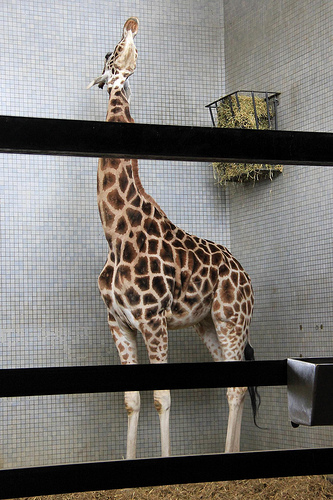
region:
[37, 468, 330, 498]
The hay on the ground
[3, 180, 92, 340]
The wall is made of tile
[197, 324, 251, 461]
The back legs of the giraffe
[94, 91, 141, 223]
The neck of the giraffe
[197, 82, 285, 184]
The bin of hay on the wall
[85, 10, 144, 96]
The head of the giraffe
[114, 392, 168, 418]
The knees of the giraffe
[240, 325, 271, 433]
The tail of the giraffe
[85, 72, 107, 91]
The ear of the giraffe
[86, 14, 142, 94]
the giraffe is holding his head up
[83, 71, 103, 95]
this is his ears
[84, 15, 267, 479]
this is a giraffe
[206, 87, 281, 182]
this is a basket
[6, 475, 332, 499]
this is the grass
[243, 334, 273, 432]
this is his tail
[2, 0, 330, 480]
this is tile on the wall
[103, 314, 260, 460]
these are the giraffes legs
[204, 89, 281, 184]
this is a basket with grass in it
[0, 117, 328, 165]
this is a rail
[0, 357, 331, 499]
A fence near the giraffe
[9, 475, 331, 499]
Hay beneath the giraffe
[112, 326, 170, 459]
The legs beneath the giraffe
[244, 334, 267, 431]
The tail of the giraffe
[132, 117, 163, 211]
The mane of the giraffe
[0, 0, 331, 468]
Walls around the giraffe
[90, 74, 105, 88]
The right ear of the giraffe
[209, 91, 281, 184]
A small cage full of hay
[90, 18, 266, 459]
A giraffe standing in an enclosure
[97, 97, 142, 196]
The giraffe has a long neck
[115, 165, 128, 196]
The spot is brown.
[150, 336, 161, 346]
The spot is brown.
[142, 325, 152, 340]
The spot is brown.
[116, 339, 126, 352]
The spot is brown.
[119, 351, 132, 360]
The spot is brown.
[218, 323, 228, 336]
The spot is brown.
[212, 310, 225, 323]
The spot is brown.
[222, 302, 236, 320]
The spot is brown.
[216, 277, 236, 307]
The spot is brown.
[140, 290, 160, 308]
The spot is brown.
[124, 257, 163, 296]
Spots on a giraffe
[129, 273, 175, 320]
Spots on a giraffe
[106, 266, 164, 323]
Spots on a giraffe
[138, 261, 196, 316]
Spots on a giraffe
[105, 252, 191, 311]
Spots on a giraffe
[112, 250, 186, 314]
Spots on a giraffe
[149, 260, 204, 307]
Spots on a giraffe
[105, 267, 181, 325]
Spots on a giraffe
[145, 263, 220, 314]
Spots on a giraffe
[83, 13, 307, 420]
tan and brown spotted giraffe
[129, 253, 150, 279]
dark brown spot on giraffe